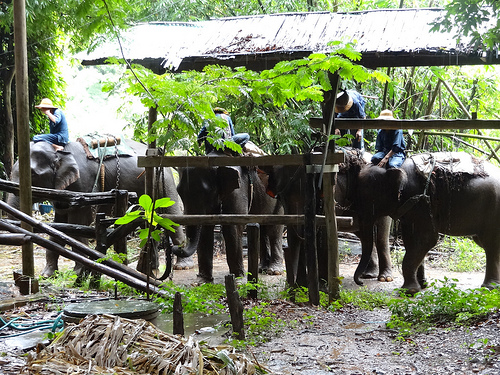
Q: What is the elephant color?
A: Gray.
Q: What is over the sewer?
A: Lid.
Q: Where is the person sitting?
A: On the elephant.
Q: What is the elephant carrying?
A: Pack.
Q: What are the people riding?
A: Elephants.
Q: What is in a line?
A: Elephants.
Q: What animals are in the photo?
A: Elephants.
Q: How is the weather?
A: Rainy.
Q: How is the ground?
A: Wet.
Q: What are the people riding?
A: The elephants.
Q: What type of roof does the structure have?
A: Thatch.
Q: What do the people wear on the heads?
A: Hats.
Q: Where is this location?
A: Safari.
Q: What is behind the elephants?
A: Pavilion.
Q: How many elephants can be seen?
A: Four.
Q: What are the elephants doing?
A: Taking a break.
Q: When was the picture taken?
A: Daytime.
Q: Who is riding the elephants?
A: Man.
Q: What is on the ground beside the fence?
A: Water.